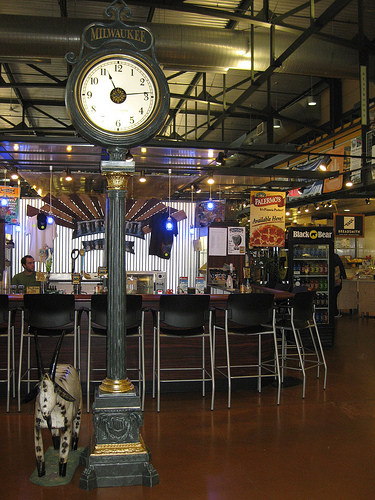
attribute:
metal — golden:
[96, 377, 141, 396]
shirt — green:
[10, 271, 46, 291]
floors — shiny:
[0, 311, 372, 498]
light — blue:
[200, 188, 224, 216]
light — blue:
[160, 206, 185, 240]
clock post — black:
[61, 3, 176, 489]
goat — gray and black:
[26, 360, 86, 472]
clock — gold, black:
[61, 0, 171, 490]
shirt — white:
[25, 213, 57, 262]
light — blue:
[158, 205, 183, 233]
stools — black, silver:
[127, 290, 302, 381]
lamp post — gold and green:
[103, 164, 137, 387]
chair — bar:
[150, 287, 219, 414]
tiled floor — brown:
[217, 424, 281, 470]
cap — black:
[34, 210, 47, 230]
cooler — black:
[281, 222, 338, 329]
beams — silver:
[0, 1, 373, 189]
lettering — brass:
[92, 26, 142, 44]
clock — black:
[64, 22, 172, 149]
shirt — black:
[145, 206, 211, 267]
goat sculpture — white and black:
[27, 328, 85, 484]